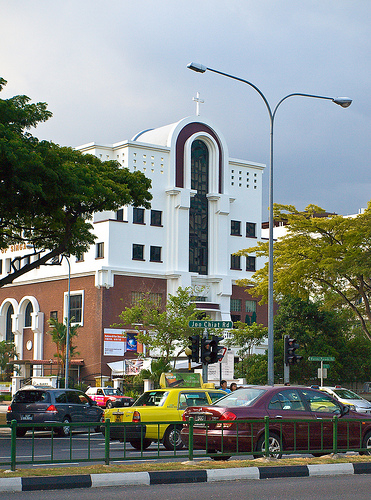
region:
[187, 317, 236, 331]
green street sign on road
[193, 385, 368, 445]
red car on street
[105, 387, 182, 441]
yellow car on street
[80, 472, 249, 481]
black and white barrier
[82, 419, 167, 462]
green metal iron fence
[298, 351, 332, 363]
green street sign on road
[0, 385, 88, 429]
blue car on road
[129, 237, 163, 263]
double windows on building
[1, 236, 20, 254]
writing on side of building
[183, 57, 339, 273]
tall double street light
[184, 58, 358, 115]
lights on a street lamp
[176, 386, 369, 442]
red four door car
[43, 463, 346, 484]
black and white stripes on ground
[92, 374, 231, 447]
yellow taxi car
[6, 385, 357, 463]
three cars in a parking lot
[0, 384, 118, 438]
grey mini van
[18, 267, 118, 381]
building with white walls and brick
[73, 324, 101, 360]
red bricks of a wall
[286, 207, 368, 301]
tree with lightgreen leaves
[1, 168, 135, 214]
tree with darkgreen leaves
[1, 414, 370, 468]
Metal bars in the middle of the roads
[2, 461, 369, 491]
Black and white curb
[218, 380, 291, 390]
People on the road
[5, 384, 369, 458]
Cars on the road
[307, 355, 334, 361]
Road sign on a pole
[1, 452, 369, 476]
Grass land strip between the bars and the curb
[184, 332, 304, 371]
Traffic light on the sidewalk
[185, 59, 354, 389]
Street lights on a pole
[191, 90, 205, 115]
Cross on the top of the building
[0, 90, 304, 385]
White and red church building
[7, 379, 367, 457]
Cars on the street.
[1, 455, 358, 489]
The curb is black and white.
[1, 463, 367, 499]
The asphalt is gray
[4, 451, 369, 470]
Green grass between curb and road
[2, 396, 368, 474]
Green metal fence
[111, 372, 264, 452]
The taxi is yellow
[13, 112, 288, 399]
White and red brick building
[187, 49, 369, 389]
Tall silver street lamp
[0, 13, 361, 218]
Sky is blue with clouds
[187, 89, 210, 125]
Large cross on top of building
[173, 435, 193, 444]
section of a fence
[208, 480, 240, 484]
edge of the road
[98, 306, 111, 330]
edge of a building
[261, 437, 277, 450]
part of a wheel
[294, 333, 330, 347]
branches of a tree